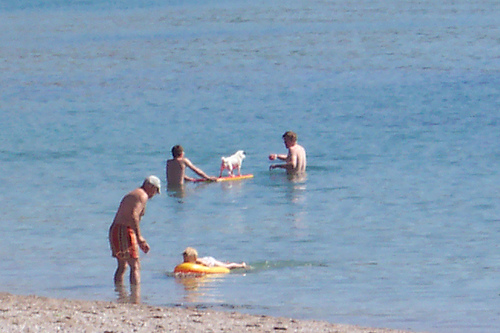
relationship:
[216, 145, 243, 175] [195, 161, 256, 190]
dog on top of paddle board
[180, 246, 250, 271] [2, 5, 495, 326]
person floating on water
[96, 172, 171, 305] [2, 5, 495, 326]
man standing in water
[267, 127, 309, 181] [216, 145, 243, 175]
person watching dog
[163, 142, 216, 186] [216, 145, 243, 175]
people watching dog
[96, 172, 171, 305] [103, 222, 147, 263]
man has swim trunks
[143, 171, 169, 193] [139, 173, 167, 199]
baseball cap on top of head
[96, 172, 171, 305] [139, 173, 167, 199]
man has head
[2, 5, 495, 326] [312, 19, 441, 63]
water has ripples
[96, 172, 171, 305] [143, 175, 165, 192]
man has baseball cap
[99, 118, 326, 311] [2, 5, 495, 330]
people are inside water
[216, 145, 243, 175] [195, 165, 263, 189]
dog on top of surfboard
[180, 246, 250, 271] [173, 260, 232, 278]
person on top of floating device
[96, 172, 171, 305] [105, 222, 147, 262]
man wearing swim trunks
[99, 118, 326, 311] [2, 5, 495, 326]
people are waist deep in water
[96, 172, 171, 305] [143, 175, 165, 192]
man wearing baseball cap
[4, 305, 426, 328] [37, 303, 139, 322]
beach has tracks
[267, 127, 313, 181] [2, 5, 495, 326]
person swimming in water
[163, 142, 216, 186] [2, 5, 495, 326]
people swimming in water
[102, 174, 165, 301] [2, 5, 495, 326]
man swimming in water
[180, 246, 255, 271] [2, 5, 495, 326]
person swimming in water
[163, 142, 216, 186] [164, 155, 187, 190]
people has back turned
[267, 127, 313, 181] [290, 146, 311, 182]
person has back turned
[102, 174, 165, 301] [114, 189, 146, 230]
man has back turned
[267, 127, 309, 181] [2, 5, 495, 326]
person inside water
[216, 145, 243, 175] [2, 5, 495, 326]
dog in water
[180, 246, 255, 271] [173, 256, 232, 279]
person on top of a floating device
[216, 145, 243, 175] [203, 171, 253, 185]
dog on top of surfboard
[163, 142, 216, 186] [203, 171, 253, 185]
people holding surfboard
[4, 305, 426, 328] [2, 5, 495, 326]
beach by water